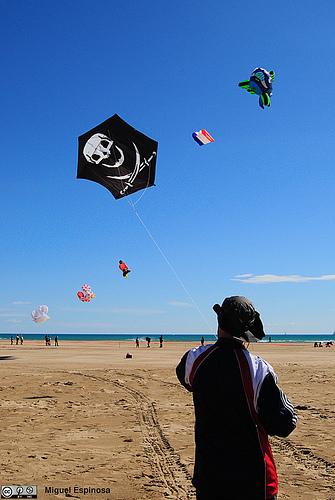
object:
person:
[176, 296, 298, 499]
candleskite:
[68, 107, 162, 196]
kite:
[238, 67, 276, 110]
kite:
[192, 128, 215, 146]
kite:
[75, 113, 160, 202]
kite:
[118, 259, 132, 277]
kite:
[77, 284, 96, 304]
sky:
[0, 0, 334, 335]